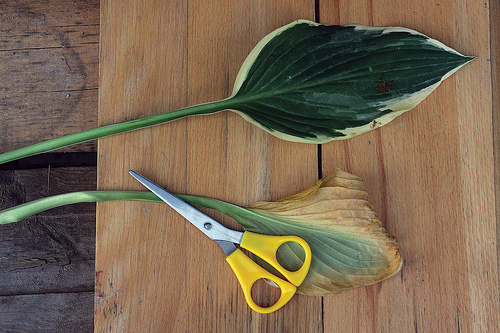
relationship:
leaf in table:
[0, 17, 481, 164] [132, 30, 472, 327]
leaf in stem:
[226, 12, 481, 152] [0, 93, 230, 170]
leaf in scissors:
[0, 17, 481, 164] [127, 167, 314, 319]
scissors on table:
[126, 168, 315, 316] [56, 69, 243, 249]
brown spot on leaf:
[292, 199, 346, 227] [196, 19, 493, 172]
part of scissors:
[243, 264, 254, 273] [126, 168, 315, 316]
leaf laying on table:
[197, 178, 405, 299] [108, 13, 424, 85]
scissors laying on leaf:
[94, 135, 329, 331] [224, 163, 417, 298]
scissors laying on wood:
[94, 135, 329, 331] [94, 1, 499, 331]